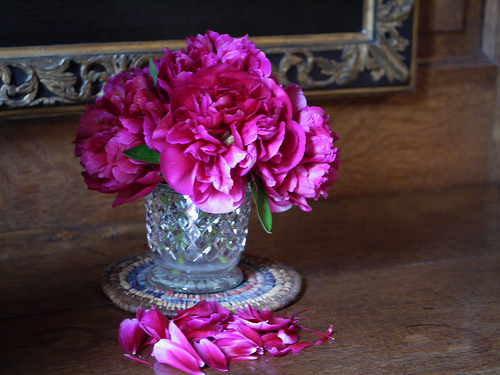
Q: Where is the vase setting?
A: In front of mirror.